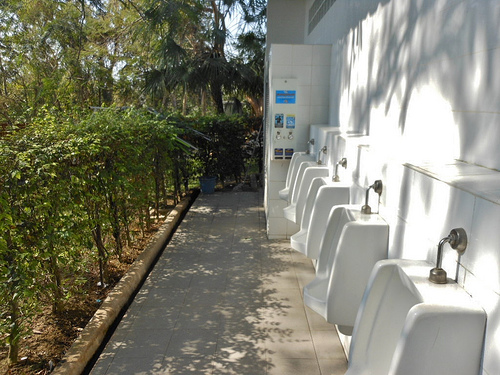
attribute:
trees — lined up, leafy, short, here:
[1, 101, 184, 365]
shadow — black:
[79, 188, 293, 373]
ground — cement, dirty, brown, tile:
[0, 182, 357, 374]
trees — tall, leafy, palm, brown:
[3, 3, 261, 116]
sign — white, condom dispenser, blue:
[271, 75, 302, 165]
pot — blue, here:
[198, 175, 221, 199]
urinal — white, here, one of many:
[294, 198, 393, 328]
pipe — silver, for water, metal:
[363, 176, 387, 214]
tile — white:
[306, 125, 498, 303]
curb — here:
[44, 187, 198, 369]